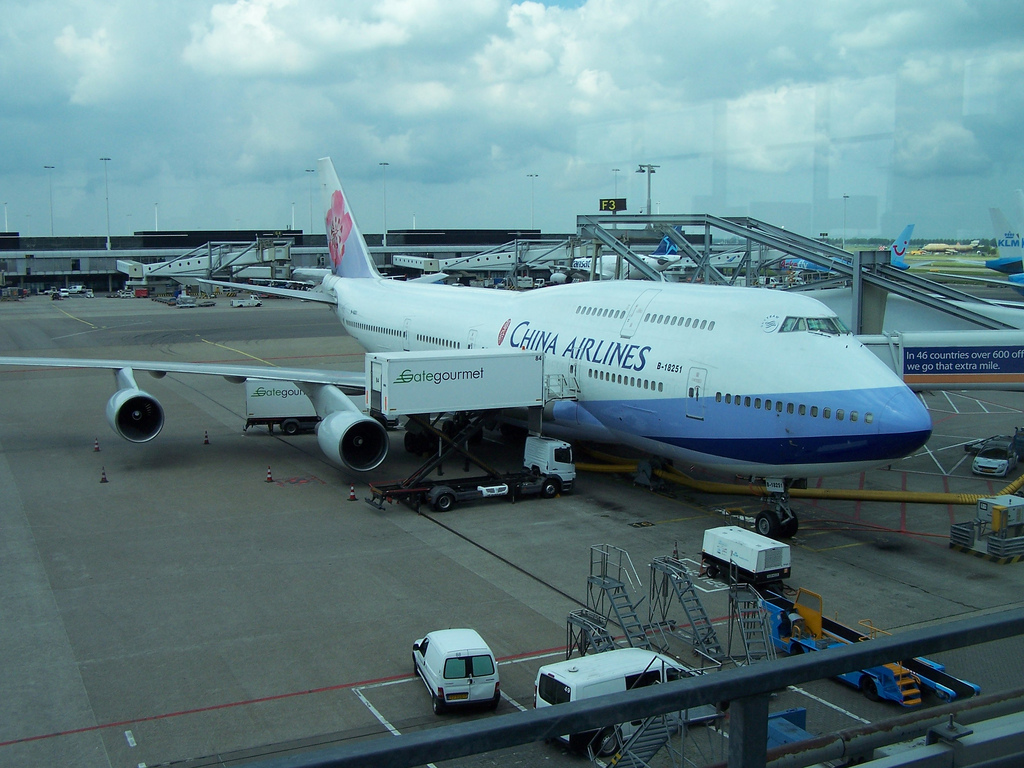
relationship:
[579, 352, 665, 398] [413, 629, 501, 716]
window on van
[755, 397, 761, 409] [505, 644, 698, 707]
window on bus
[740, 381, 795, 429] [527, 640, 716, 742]
window on a bus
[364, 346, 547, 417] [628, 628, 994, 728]
white cart on side of building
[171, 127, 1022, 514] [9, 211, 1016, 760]
airplane parked at airport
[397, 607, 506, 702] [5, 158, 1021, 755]
van at airport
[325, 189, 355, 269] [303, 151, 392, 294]
pink logo on tail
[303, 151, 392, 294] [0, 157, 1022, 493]
tail on airplane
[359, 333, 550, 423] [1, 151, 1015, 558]
white cart against airplane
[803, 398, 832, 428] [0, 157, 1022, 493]
window on airplane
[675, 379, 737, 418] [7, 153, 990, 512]
window on bus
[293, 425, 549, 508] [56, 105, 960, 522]
cart under airplane